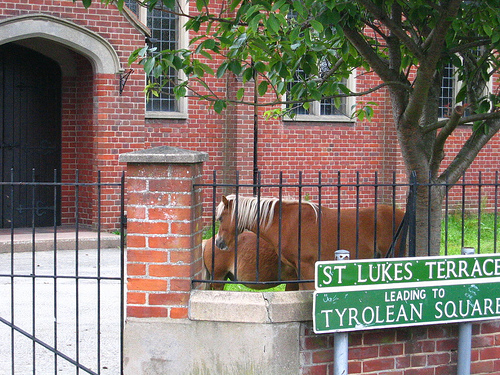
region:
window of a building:
[149, 0, 177, 20]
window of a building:
[142, 29, 177, 44]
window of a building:
[150, 35, 177, 49]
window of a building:
[149, 95, 183, 109]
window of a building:
[327, 102, 345, 112]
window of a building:
[443, 82, 457, 96]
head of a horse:
[197, 179, 271, 247]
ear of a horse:
[213, 178, 235, 209]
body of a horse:
[277, 182, 465, 270]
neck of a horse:
[245, 175, 315, 245]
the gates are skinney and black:
[21, 287, 123, 370]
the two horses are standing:
[219, 160, 406, 261]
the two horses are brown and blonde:
[214, 201, 390, 263]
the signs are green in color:
[317, 292, 497, 323]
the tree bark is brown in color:
[396, 117, 461, 246]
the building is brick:
[105, 109, 132, 143]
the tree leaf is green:
[227, 82, 374, 112]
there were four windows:
[139, 80, 205, 131]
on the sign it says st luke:
[324, 267, 414, 279]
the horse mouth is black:
[213, 237, 221, 246]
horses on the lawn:
[203, 172, 402, 292]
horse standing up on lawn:
[215, 187, 415, 277]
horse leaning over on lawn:
[203, 234, 313, 296]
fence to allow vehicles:
[2, 180, 120, 374]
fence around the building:
[209, 173, 494, 276]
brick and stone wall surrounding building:
[127, 325, 489, 373]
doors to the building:
[4, 60, 69, 211]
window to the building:
[288, 28, 348, 125]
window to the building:
[149, 5, 182, 105]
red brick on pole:
[128, 192, 173, 209]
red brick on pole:
[126, 157, 173, 179]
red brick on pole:
[156, 180, 187, 199]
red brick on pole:
[127, 232, 150, 244]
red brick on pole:
[150, 232, 202, 253]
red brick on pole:
[171, 249, 194, 264]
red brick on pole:
[148, 268, 187, 291]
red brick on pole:
[124, 277, 171, 314]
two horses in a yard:
[200, 196, 405, 293]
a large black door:
[0, 43, 60, 223]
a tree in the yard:
[84, 2, 499, 249]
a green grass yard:
[205, 215, 497, 293]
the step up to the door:
[0, 225, 121, 250]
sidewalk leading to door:
[0, 247, 123, 374]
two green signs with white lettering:
[312, 255, 497, 334]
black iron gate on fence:
[2, 166, 124, 373]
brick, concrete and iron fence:
[119, 149, 499, 374]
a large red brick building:
[0, 0, 493, 222]